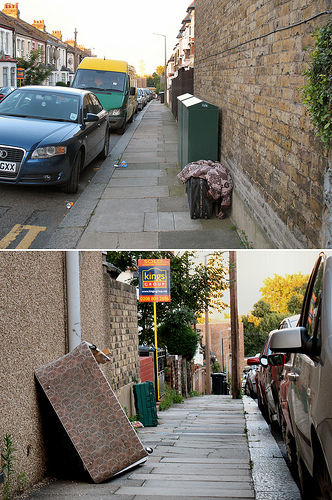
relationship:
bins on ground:
[166, 86, 230, 178] [232, 53, 250, 77]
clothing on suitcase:
[177, 159, 249, 216] [184, 177, 212, 223]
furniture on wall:
[33, 341, 152, 482] [0, 250, 141, 498]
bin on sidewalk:
[132, 379, 158, 426] [21, 394, 303, 499]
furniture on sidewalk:
[33, 341, 152, 482] [63, 398, 247, 498]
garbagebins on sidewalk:
[212, 367, 232, 396] [189, 384, 250, 414]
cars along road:
[244, 252, 331, 499] [253, 397, 319, 499]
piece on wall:
[36, 341, 151, 478] [4, 249, 116, 494]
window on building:
[15, 38, 29, 57] [23, 44, 47, 57]